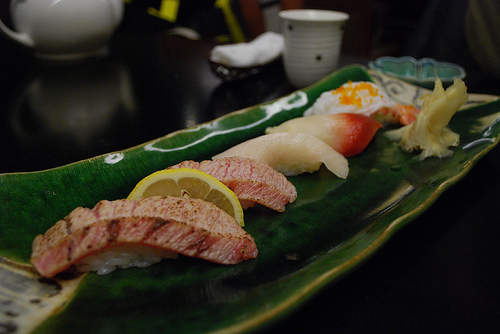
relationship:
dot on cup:
[314, 55, 323, 62] [278, 5, 357, 92]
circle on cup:
[313, 52, 328, 64] [278, 5, 357, 92]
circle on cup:
[316, 55, 323, 61] [278, 5, 351, 87]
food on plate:
[29, 82, 387, 278] [24, 61, 492, 325]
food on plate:
[29, 82, 387, 278] [11, 55, 498, 307]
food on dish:
[43, 90, 381, 272] [3, 63, 499, 328]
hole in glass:
[315, 54, 323, 61] [277, 6, 356, 95]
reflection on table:
[5, 55, 135, 165] [98, 44, 188, 131]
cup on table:
[278, 5, 351, 87] [22, 69, 241, 114]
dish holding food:
[3, 63, 499, 328] [43, 90, 381, 272]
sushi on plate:
[31, 75, 470, 278] [24, 61, 492, 325]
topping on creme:
[329, 74, 390, 120] [297, 78, 395, 122]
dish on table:
[3, 63, 499, 328] [0, 21, 497, 331]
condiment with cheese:
[333, 80, 381, 105] [339, 79, 369, 105]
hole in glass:
[309, 50, 325, 65] [277, 8, 350, 89]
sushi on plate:
[4, 64, 496, 330] [8, 73, 488, 332]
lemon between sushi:
[126, 168, 245, 227] [32, 133, 292, 263]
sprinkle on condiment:
[309, 76, 402, 116] [306, 72, 411, 124]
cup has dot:
[278, 8, 351, 87] [310, 48, 324, 64]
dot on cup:
[282, 19, 296, 31] [278, 5, 351, 87]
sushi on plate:
[31, 75, 470, 278] [19, 174, 233, 314]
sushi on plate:
[31, 75, 470, 278] [101, 70, 499, 331]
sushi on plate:
[4, 64, 496, 330] [24, 61, 492, 325]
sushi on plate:
[31, 75, 470, 278] [13, 39, 496, 331]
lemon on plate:
[126, 168, 245, 227] [24, 61, 492, 325]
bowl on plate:
[368, 55, 466, 90] [13, 39, 496, 331]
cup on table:
[278, 8, 351, 87] [99, 48, 428, 157]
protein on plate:
[17, 183, 269, 288] [24, 61, 492, 325]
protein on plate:
[173, 152, 302, 222] [24, 61, 492, 325]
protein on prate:
[268, 101, 402, 155] [17, 46, 498, 315]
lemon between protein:
[124, 157, 247, 229] [13, 148, 303, 275]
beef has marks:
[30, 194, 260, 279] [97, 217, 218, 255]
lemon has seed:
[126, 168, 245, 227] [177, 183, 191, 197]